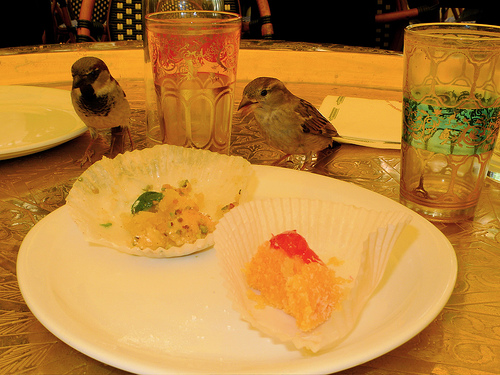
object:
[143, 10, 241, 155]
glass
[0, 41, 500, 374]
table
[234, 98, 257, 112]
beak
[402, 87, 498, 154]
green accents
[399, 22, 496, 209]
gold accents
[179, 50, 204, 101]
glass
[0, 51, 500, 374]
table top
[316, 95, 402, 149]
napkin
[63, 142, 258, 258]
food paper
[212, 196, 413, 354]
food paper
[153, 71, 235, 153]
water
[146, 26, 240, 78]
design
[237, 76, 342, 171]
birds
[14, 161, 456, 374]
plate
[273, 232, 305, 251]
red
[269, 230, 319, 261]
cherry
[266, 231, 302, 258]
top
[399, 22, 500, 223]
glass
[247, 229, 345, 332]
food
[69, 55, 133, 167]
bird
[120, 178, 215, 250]
pastry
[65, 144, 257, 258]
paper cup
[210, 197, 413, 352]
paper cup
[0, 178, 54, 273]
gold design